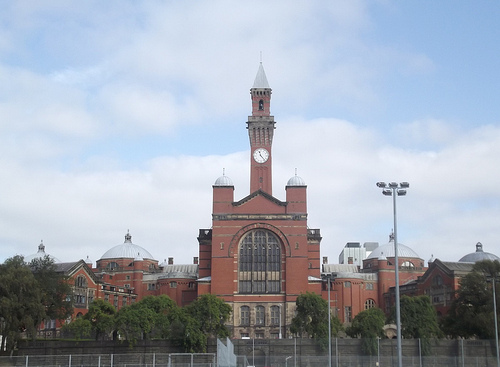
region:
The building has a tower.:
[240, 50, 283, 200]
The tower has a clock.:
[244, 141, 272, 171]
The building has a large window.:
[224, 217, 295, 304]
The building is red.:
[182, 85, 350, 337]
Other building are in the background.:
[11, 221, 203, 343]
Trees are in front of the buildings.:
[0, 242, 233, 359]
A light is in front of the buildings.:
[375, 165, 425, 365]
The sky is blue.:
[345, 0, 497, 122]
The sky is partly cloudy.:
[0, 0, 375, 152]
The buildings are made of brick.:
[53, 217, 447, 315]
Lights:
[358, 150, 459, 304]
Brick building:
[215, 183, 391, 340]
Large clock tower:
[241, 65, 327, 297]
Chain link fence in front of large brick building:
[77, 265, 246, 362]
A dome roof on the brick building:
[78, 176, 180, 294]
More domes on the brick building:
[369, 218, 491, 282]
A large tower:
[236, 83, 296, 223]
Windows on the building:
[221, 192, 302, 325]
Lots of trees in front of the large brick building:
[17, 225, 251, 363]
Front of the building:
[174, 295, 312, 342]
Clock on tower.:
[250, 142, 269, 163]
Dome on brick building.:
[97, 225, 160, 262]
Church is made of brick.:
[17, 49, 498, 326]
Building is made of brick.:
[0, 50, 492, 322]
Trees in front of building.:
[2, 254, 229, 359]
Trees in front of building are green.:
[3, 250, 231, 351]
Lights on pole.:
[380, 177, 412, 363]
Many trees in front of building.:
[4, 254, 498, 354]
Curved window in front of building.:
[233, 222, 290, 302]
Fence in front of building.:
[3, 332, 498, 364]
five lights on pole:
[373, 176, 416, 213]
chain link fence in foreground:
[122, 350, 184, 365]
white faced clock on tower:
[249, 141, 271, 166]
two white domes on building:
[208, 171, 315, 196]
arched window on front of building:
[226, 218, 288, 305]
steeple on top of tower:
[251, 54, 268, 94]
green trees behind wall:
[83, 296, 238, 351]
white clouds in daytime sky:
[333, 87, 450, 159]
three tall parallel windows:
[231, 301, 288, 332]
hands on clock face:
[252, 147, 267, 164]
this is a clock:
[246, 139, 273, 163]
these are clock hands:
[253, 145, 270, 162]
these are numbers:
[249, 140, 276, 176]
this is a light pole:
[370, 160, 437, 365]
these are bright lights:
[352, 167, 425, 204]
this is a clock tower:
[238, 60, 294, 206]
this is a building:
[14, 60, 475, 365]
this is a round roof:
[93, 224, 168, 267]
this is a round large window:
[218, 214, 298, 299]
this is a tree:
[172, 276, 242, 364]